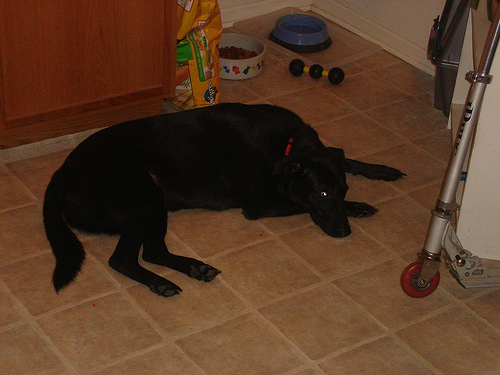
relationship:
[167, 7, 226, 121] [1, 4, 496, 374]
bag on floor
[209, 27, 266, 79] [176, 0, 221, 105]
bowl of food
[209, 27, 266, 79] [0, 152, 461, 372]
bowl on floor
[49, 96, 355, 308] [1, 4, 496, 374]
black dog on floor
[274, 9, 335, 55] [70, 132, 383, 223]
bowl for dog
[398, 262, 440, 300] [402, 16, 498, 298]
wheel of scooter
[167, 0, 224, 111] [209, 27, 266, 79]
bag by bowl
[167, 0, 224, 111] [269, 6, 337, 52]
bag by bowl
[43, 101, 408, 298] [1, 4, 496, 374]
black dog lying on floor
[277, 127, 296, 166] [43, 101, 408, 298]
collar on black dog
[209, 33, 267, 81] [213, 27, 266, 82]
bowl on bowl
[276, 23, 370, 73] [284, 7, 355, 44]
water on bowl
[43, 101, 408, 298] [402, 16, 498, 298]
black dog on scooter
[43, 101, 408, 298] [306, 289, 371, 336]
black dog on floor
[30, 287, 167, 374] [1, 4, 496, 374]
tile on floor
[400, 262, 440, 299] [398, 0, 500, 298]
wheel on scooter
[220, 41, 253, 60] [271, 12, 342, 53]
food in bowl